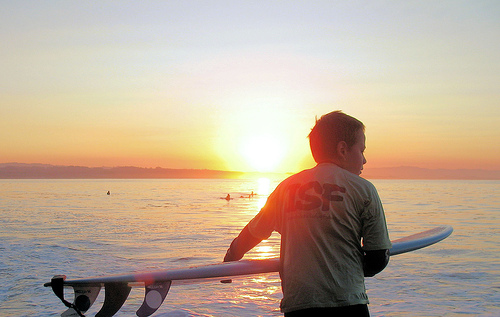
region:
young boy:
[254, 112, 405, 299]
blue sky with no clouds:
[18, 32, 78, 74]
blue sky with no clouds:
[340, 28, 387, 55]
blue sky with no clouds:
[431, 65, 476, 107]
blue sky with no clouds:
[130, 53, 198, 91]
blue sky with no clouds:
[34, 33, 78, 68]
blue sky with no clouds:
[104, 1, 146, 45]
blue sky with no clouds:
[17, 58, 68, 100]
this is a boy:
[267, 107, 388, 314]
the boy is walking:
[271, 102, 381, 312]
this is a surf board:
[42, 254, 228, 311]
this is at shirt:
[283, 175, 363, 296]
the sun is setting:
[218, 107, 285, 166]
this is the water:
[59, 192, 169, 262]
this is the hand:
[227, 217, 272, 251]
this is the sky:
[83, 17, 244, 84]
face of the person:
[303, 100, 413, 200]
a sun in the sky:
[221, 134, 292, 216]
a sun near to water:
[221, 143, 291, 190]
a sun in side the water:
[218, 130, 310, 206]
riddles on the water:
[69, 193, 130, 234]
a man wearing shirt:
[241, 125, 393, 307]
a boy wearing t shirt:
[257, 175, 385, 294]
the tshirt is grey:
[263, 164, 380, 306]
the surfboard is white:
[62, 221, 457, 286]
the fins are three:
[62, 287, 166, 316]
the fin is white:
[68, 289, 92, 316]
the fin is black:
[103, 287, 136, 313]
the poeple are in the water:
[99, 184, 263, 209]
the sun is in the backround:
[203, 122, 304, 184]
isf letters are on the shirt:
[278, 177, 355, 227]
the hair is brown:
[300, 110, 365, 157]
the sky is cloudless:
[61, 27, 486, 93]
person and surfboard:
[56, 112, 441, 314]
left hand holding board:
[36, 249, 242, 297]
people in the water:
[195, 185, 258, 200]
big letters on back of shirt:
[284, 184, 350, 211]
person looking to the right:
[267, 105, 417, 198]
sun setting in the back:
[210, 131, 305, 178]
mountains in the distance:
[0, 154, 197, 180]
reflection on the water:
[237, 181, 282, 302]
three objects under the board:
[43, 285, 173, 315]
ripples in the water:
[438, 185, 488, 314]